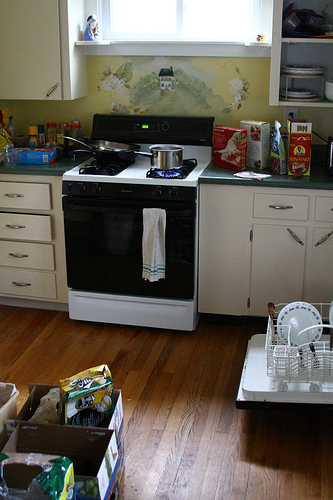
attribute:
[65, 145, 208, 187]
stove top — gas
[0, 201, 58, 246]
kitchen drawer — partially open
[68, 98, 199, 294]
stove — large, black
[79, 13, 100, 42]
figurine — small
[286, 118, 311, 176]
box — large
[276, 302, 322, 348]
plates — white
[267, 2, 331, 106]
cabinet — kitchen 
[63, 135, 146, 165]
skillets — pair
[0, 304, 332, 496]
floors — wooden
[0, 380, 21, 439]
trash can — trash , corner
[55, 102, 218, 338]
stove — black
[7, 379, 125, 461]
box — cardboard, open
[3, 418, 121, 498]
box — open, cardboard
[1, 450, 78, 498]
box — open, cardboard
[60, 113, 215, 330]
stove — gas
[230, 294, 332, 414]
dish washer — dish 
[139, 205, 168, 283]
towel — white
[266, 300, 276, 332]
spoon — wooden